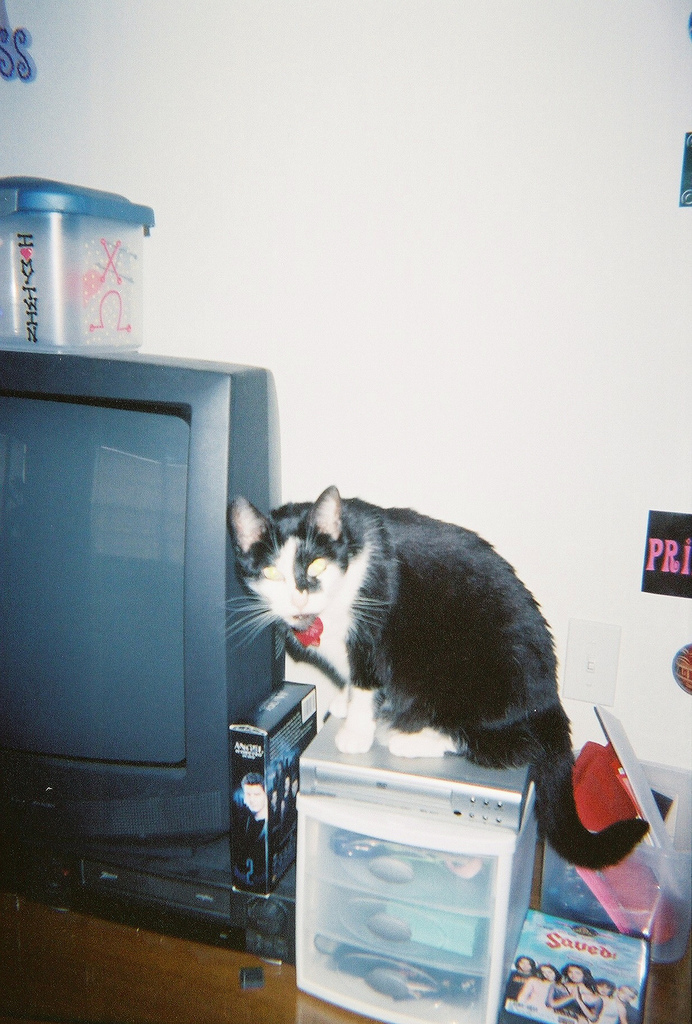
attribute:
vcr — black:
[10, 847, 304, 965]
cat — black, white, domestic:
[226, 475, 657, 875]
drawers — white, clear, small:
[276, 782, 541, 1014]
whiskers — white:
[211, 584, 392, 638]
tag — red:
[286, 604, 325, 651]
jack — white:
[551, 609, 626, 718]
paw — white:
[329, 678, 390, 763]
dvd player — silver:
[288, 689, 545, 832]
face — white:
[228, 491, 355, 631]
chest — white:
[278, 577, 383, 690]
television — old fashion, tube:
[1, 330, 318, 873]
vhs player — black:
[5, 816, 337, 988]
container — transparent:
[527, 726, 671, 958]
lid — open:
[583, 691, 668, 860]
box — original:
[225, 681, 323, 907]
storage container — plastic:
[5, 210, 161, 353]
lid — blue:
[3, 168, 160, 235]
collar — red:
[290, 594, 329, 659]